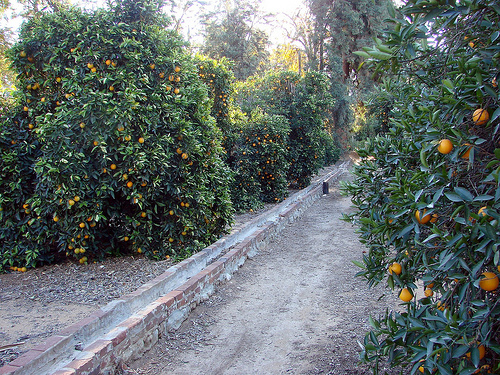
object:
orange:
[434, 137, 456, 157]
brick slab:
[2, 158, 354, 372]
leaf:
[366, 49, 396, 61]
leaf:
[421, 142, 435, 154]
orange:
[164, 254, 171, 260]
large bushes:
[0, 2, 238, 275]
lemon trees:
[0, 0, 237, 276]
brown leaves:
[0, 158, 426, 374]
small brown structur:
[322, 179, 330, 194]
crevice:
[0, 157, 355, 375]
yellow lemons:
[458, 143, 473, 160]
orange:
[415, 208, 433, 225]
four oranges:
[9, 266, 27, 273]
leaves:
[173, 225, 200, 252]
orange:
[388, 262, 403, 276]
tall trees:
[308, 0, 407, 157]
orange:
[269, 139, 272, 143]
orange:
[326, 118, 330, 123]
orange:
[67, 199, 75, 206]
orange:
[19, 49, 27, 58]